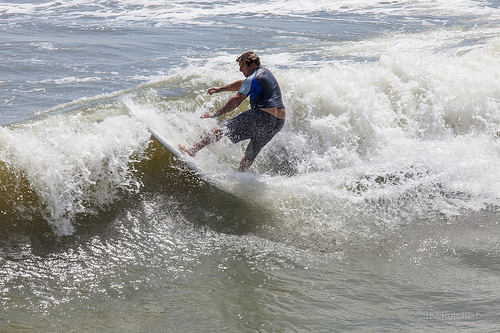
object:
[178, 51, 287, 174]
man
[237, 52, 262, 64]
hair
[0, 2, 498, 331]
water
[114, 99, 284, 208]
board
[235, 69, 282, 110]
shirt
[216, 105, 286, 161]
shorts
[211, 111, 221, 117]
bracelet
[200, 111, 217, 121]
hands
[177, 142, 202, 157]
feet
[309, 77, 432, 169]
foaming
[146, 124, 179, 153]
white